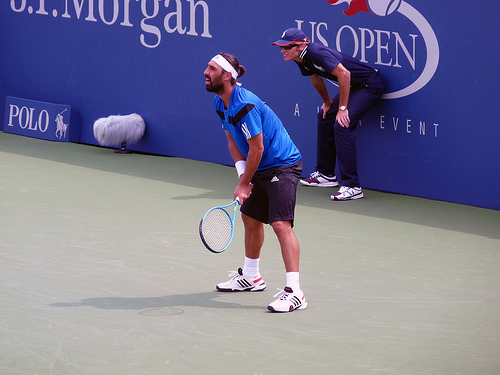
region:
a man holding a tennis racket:
[172, 50, 313, 316]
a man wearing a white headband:
[187, 42, 256, 92]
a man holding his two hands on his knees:
[273, 22, 401, 177]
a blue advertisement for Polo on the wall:
[5, 85, 80, 144]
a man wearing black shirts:
[231, 167, 301, 235]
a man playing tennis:
[164, 41, 302, 316]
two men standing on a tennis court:
[169, 28, 412, 315]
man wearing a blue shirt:
[217, 100, 298, 162]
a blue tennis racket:
[192, 200, 247, 252]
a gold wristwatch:
[332, 102, 352, 114]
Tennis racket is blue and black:
[192, 193, 248, 256]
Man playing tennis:
[195, 50, 312, 314]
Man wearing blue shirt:
[187, 50, 316, 321]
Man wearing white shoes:
[202, 264, 314, 320]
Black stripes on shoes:
[207, 264, 314, 319]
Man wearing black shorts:
[190, 42, 312, 319]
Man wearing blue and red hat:
[271, 27, 404, 204]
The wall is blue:
[0, 0, 498, 210]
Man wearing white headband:
[187, 40, 319, 332]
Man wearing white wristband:
[190, 35, 313, 322]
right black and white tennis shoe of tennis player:
[268, 287, 311, 311]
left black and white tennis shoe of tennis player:
[213, 267, 266, 293]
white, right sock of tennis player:
[282, 270, 303, 294]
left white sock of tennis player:
[242, 254, 259, 277]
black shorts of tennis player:
[238, 160, 310, 225]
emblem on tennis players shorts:
[269, 175, 281, 185]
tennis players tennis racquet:
[195, 195, 242, 254]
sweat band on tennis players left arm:
[231, 158, 250, 175]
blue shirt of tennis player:
[204, 80, 303, 170]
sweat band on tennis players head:
[204, 53, 239, 79]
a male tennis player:
[196, 51, 310, 313]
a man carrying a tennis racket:
[200, 48, 309, 313]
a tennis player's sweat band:
[209, 53, 237, 81]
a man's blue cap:
[272, 27, 309, 45]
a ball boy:
[273, 27, 388, 199]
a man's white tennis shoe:
[263, 284, 308, 311]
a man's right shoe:
[216, 268, 264, 293]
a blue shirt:
[212, 86, 302, 162]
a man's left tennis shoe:
[330, 181, 364, 203]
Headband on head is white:
[209, 53, 239, 80]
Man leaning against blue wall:
[272, 24, 392, 201]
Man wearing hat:
[274, 22, 389, 206]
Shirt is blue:
[214, 83, 306, 177]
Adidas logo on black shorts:
[269, 166, 281, 183]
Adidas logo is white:
[269, 174, 281, 184]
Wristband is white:
[231, 160, 247, 177]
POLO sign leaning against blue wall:
[0, 86, 73, 143]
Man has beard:
[195, 47, 307, 313]